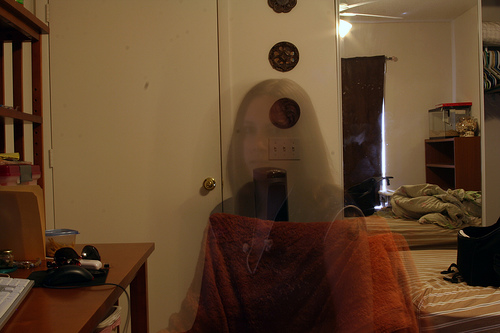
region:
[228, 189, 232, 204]
part of a knob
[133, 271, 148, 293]
part of a table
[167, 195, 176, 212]
edge of a door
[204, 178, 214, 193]
part of a knob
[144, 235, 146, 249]
part of a table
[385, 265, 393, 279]
part of a towel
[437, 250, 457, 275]
edge of a bed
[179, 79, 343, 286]
a ghost shape of woman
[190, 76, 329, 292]
a ghost shape of woman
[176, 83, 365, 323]
a ghost shape of woman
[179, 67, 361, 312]
a ghost shape of woman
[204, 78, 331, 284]
a ghost shape of woman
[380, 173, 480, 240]
reflection of unmade bed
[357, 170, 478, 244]
reflection of unmade bed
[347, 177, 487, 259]
reflection of unmade bed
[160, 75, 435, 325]
Reflection of a girl.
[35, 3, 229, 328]
White door on a wall.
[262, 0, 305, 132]
Three round objects on the wall.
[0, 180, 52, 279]
Brown file on a desk.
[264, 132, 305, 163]
Light switch near a door.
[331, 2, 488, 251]
Mirror on a wall.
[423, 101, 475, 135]
Aquarium on a bookshelf.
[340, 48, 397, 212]
Brown curtains on a window.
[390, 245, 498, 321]
Gold and white striped sheets.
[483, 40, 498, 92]
Clothes hangers in a closet.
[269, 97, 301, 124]
a black circle handing on the wall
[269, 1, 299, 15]
a black circle handing on the wall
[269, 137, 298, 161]
the white set of light switches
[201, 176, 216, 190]
the brass door knob with lock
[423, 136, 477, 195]
a wooden bookcase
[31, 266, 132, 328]
a black corded mouse on the desk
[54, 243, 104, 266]
a pair of black sunglasses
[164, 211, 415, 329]
an orange towel on the chair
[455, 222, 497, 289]
a bag on the bed